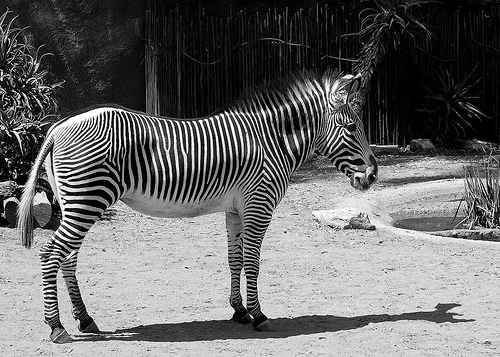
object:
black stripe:
[63, 220, 100, 227]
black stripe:
[61, 199, 106, 209]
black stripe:
[59, 120, 113, 137]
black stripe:
[57, 179, 119, 198]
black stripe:
[49, 162, 124, 178]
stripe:
[357, 143, 365, 163]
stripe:
[326, 151, 351, 162]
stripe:
[224, 108, 240, 191]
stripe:
[192, 120, 204, 138]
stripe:
[260, 196, 280, 205]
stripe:
[106, 114, 129, 136]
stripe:
[275, 96, 300, 162]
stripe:
[128, 187, 217, 196]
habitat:
[1, 0, 499, 356]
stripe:
[197, 172, 210, 201]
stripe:
[302, 97, 330, 121]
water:
[393, 212, 499, 245]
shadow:
[72, 302, 476, 343]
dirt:
[92, 250, 200, 293]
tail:
[17, 133, 55, 251]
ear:
[330, 74, 355, 108]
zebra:
[19, 72, 380, 345]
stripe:
[47, 291, 57, 313]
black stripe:
[171, 148, 211, 172]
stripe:
[230, 234, 247, 254]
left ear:
[349, 73, 363, 101]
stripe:
[47, 259, 60, 287]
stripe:
[58, 179, 75, 188]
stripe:
[61, 145, 74, 171]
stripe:
[45, 302, 61, 318]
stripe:
[240, 262, 257, 278]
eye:
[346, 124, 357, 131]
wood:
[1, 181, 58, 230]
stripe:
[50, 226, 84, 236]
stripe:
[328, 140, 358, 155]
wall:
[9, 12, 499, 192]